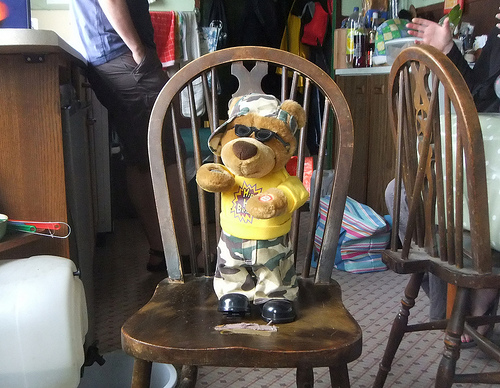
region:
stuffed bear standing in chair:
[188, 88, 323, 330]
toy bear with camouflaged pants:
[193, 90, 315, 321]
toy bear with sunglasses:
[190, 91, 317, 326]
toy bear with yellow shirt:
[184, 91, 322, 331]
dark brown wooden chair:
[115, 41, 364, 386]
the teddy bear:
[195, 85, 312, 322]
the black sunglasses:
[226, 118, 290, 145]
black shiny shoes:
[215, 291, 295, 322]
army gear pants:
[211, 227, 301, 305]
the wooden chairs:
[118, 39, 498, 386]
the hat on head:
[204, 88, 307, 159]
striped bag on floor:
[306, 189, 390, 277]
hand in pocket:
[128, 42, 158, 82]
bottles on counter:
[338, 0, 387, 67]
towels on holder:
[149, 5, 204, 119]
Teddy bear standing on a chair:
[196, 93, 310, 323]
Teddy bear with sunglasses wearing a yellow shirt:
[195, 91, 307, 322]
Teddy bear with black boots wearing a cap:
[192, 90, 307, 320]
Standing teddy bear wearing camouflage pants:
[193, 91, 304, 317]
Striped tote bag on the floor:
[311, 188, 390, 274]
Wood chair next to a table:
[371, 43, 499, 387]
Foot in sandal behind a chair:
[443, 273, 498, 351]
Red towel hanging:
[145, 7, 175, 65]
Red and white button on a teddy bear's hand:
[254, 190, 279, 210]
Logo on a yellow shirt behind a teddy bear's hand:
[226, 180, 269, 224]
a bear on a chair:
[178, 84, 318, 309]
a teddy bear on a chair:
[191, 69, 336, 354]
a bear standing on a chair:
[157, 88, 332, 374]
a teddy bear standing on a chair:
[174, 77, 383, 369]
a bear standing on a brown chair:
[199, 51, 367, 386]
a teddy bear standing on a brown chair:
[182, 36, 354, 383]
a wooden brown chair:
[164, 30, 378, 387]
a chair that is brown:
[139, 40, 353, 382]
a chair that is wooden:
[148, 40, 417, 387]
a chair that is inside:
[154, 42, 361, 368]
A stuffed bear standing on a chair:
[198, 99, 316, 330]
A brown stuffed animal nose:
[228, 136, 265, 163]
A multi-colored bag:
[318, 188, 390, 278]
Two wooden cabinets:
[332, 74, 417, 221]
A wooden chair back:
[121, 56, 363, 286]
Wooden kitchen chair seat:
[128, 278, 345, 370]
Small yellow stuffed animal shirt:
[209, 167, 289, 237]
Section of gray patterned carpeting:
[351, 278, 394, 311]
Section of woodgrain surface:
[16, 96, 46, 199]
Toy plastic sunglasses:
[232, 120, 270, 141]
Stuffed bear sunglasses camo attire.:
[190, 89, 321, 326]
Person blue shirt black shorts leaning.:
[72, 3, 184, 175]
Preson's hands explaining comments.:
[402, 0, 499, 57]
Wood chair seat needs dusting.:
[388, 196, 496, 296]